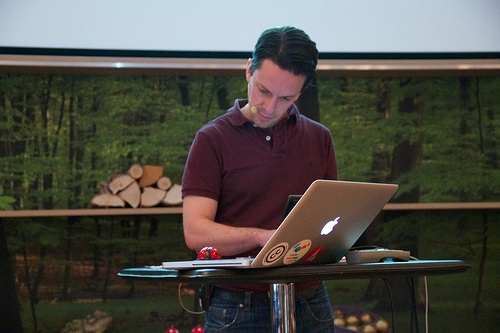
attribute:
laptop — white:
[159, 172, 397, 270]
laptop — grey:
[151, 167, 415, 273]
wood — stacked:
[89, 164, 181, 208]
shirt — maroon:
[178, 97, 341, 292]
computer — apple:
[159, 173, 406, 270]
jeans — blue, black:
[200, 276, 341, 328]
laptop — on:
[163, 173, 408, 283]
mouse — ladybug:
[197, 244, 219, 261]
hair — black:
[249, 26, 317, 88]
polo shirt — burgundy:
[180, 96, 339, 294]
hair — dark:
[247, 27, 318, 94]